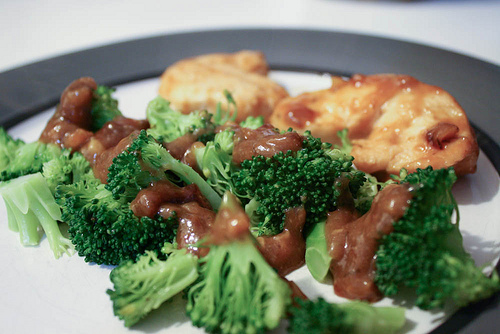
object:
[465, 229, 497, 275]
shadow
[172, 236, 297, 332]
broccoli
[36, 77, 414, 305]
brown sauce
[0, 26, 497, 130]
edge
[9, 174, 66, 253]
broccoli stem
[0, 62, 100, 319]
plate edge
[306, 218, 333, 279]
broccoli stem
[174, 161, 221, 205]
broccoli stem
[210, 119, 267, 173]
noobject tobox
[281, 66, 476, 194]
cooked potato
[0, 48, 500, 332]
food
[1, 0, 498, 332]
table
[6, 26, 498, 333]
plate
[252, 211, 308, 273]
brown sauce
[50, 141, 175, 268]
broccoli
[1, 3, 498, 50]
counter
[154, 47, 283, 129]
meat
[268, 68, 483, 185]
meat